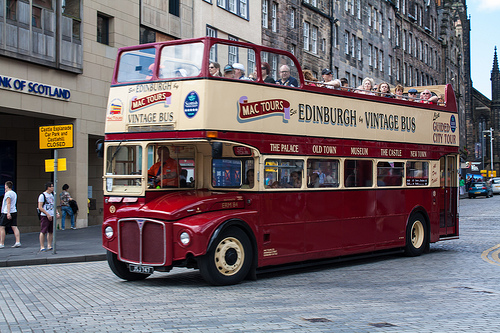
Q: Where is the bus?
A: City street.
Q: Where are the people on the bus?
A: Top.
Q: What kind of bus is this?
A: Double decker.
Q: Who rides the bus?
A: Tourists.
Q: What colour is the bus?
A: Burgundy and cream.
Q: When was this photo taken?
A: During the afternoon.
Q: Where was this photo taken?
A: On the road.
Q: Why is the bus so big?
A: It is a double decker.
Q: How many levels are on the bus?
A: 2.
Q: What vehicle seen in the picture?
A: Bus.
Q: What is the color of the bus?
A: Red and ivory.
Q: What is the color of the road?
A: Grey.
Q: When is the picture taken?
A: Daytime.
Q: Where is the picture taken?
A: On a city street.